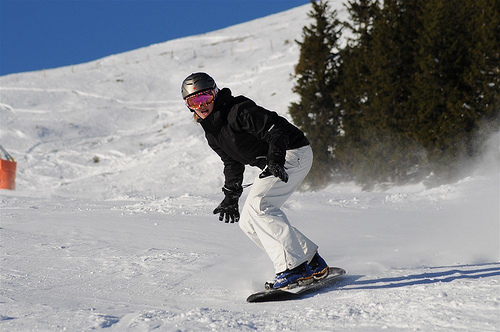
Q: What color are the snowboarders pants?
A: White.